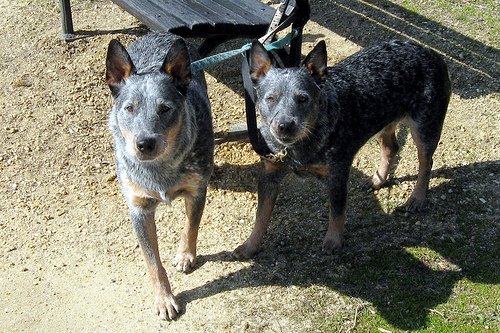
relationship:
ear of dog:
[243, 32, 274, 78] [229, 38, 453, 266]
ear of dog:
[243, 32, 274, 78] [81, 27, 231, 320]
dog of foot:
[229, 38, 453, 266] [317, 228, 341, 255]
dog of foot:
[229, 38, 453, 266] [391, 191, 426, 216]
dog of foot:
[229, 38, 453, 266] [152, 291, 182, 321]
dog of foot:
[229, 38, 453, 266] [168, 252, 197, 273]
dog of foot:
[229, 38, 453, 266] [226, 243, 261, 258]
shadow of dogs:
[180, 163, 497, 331] [103, 29, 451, 326]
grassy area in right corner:
[258, 196, 498, 331] [328, 241, 499, 328]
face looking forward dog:
[110, 67, 185, 160] [229, 38, 453, 266]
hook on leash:
[262, 147, 290, 162] [187, 30, 297, 75]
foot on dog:
[171, 251, 199, 272] [229, 38, 453, 266]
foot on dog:
[228, 221, 268, 262] [226, 21, 465, 263]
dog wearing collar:
[229, 38, 453, 266] [274, 141, 298, 163]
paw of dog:
[230, 240, 260, 260] [229, 38, 453, 266]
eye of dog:
[262, 86, 277, 107] [246, 32, 443, 252]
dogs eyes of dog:
[126, 104, 172, 111] [229, 38, 453, 266]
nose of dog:
[133, 134, 158, 154] [87, 24, 235, 329]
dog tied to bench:
[229, 38, 453, 266] [57, 0, 309, 82]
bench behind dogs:
[52, 0, 312, 142] [230, 39, 452, 261]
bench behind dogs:
[52, 0, 312, 142] [104, 27, 215, 320]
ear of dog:
[243, 32, 274, 78] [81, 42, 431, 274]